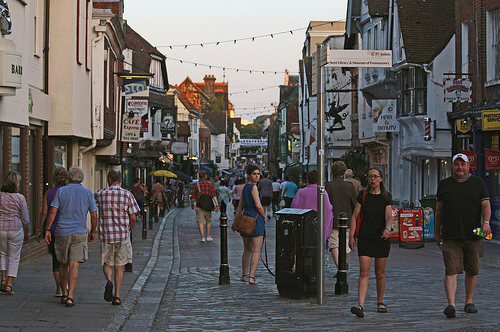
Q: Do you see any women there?
A: Yes, there is a woman.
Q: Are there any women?
A: Yes, there is a woman.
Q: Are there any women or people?
A: Yes, there is a woman.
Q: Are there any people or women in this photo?
A: Yes, there is a woman.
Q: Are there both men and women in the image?
A: Yes, there are both a woman and a man.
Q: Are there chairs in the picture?
A: No, there are no chairs.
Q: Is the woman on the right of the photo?
A: Yes, the woman is on the right of the image.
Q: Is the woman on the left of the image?
A: No, the woman is on the right of the image.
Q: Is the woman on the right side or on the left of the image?
A: The woman is on the right of the image.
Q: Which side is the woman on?
A: The woman is on the right of the image.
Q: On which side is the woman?
A: The woman is on the right of the image.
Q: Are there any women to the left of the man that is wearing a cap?
A: Yes, there is a woman to the left of the man.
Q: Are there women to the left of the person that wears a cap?
A: Yes, there is a woman to the left of the man.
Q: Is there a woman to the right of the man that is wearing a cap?
A: No, the woman is to the left of the man.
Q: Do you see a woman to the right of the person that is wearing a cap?
A: No, the woman is to the left of the man.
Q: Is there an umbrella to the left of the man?
A: No, there is a woman to the left of the man.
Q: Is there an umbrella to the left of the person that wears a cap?
A: No, there is a woman to the left of the man.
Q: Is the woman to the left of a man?
A: Yes, the woman is to the left of a man.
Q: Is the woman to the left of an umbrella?
A: No, the woman is to the left of a man.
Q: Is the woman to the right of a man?
A: No, the woman is to the left of a man.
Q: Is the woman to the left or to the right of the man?
A: The woman is to the left of the man.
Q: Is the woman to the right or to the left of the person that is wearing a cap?
A: The woman is to the left of the man.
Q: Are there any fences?
A: No, there are no fences.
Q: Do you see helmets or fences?
A: No, there are no fences or helmets.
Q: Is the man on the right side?
A: Yes, the man is on the right of the image.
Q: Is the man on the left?
A: No, the man is on the right of the image.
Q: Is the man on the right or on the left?
A: The man is on the right of the image.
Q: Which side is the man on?
A: The man is on the right of the image.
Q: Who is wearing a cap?
A: The man is wearing a cap.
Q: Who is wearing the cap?
A: The man is wearing a cap.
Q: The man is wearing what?
A: The man is wearing a cap.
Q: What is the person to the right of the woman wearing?
A: The man is wearing a cap.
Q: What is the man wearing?
A: The man is wearing a cap.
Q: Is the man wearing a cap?
A: Yes, the man is wearing a cap.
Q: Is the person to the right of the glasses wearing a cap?
A: Yes, the man is wearing a cap.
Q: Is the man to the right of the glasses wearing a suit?
A: No, the man is wearing a cap.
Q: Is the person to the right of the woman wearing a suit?
A: No, the man is wearing a cap.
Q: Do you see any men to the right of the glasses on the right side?
A: Yes, there is a man to the right of the glasses.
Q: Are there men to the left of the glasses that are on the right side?
A: No, the man is to the right of the glasses.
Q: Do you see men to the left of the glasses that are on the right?
A: No, the man is to the right of the glasses.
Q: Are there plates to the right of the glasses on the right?
A: No, there is a man to the right of the glasses.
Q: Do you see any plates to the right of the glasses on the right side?
A: No, there is a man to the right of the glasses.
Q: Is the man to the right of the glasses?
A: Yes, the man is to the right of the glasses.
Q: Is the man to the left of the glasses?
A: No, the man is to the right of the glasses.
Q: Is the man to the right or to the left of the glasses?
A: The man is to the right of the glasses.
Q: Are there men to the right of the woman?
A: Yes, there is a man to the right of the woman.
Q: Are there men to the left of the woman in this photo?
A: No, the man is to the right of the woman.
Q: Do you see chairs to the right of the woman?
A: No, there is a man to the right of the woman.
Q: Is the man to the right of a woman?
A: Yes, the man is to the right of a woman.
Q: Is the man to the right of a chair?
A: No, the man is to the right of a woman.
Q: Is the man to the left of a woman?
A: No, the man is to the right of a woman.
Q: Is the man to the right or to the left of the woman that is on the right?
A: The man is to the right of the woman.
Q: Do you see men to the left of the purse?
A: No, the man is to the right of the purse.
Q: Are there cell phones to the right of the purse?
A: No, there is a man to the right of the purse.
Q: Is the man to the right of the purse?
A: Yes, the man is to the right of the purse.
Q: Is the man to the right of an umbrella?
A: No, the man is to the right of the purse.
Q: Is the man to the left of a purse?
A: No, the man is to the right of a purse.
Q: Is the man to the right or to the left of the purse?
A: The man is to the right of the purse.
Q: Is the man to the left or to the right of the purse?
A: The man is to the right of the purse.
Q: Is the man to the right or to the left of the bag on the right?
A: The man is to the right of the purse.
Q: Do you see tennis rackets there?
A: No, there are no tennis rackets.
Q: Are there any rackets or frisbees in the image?
A: No, there are no rackets or frisbees.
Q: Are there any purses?
A: Yes, there is a purse.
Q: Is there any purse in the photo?
A: Yes, there is a purse.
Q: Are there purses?
A: Yes, there is a purse.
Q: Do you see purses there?
A: Yes, there is a purse.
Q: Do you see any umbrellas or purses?
A: Yes, there is a purse.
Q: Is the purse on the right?
A: Yes, the purse is on the right of the image.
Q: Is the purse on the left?
A: No, the purse is on the right of the image.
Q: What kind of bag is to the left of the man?
A: The bag is a purse.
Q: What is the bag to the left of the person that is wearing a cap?
A: The bag is a purse.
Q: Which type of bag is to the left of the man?
A: The bag is a purse.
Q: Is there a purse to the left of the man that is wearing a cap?
A: Yes, there is a purse to the left of the man.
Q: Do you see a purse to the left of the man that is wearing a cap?
A: Yes, there is a purse to the left of the man.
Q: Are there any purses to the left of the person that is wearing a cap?
A: Yes, there is a purse to the left of the man.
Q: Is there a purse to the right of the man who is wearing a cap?
A: No, the purse is to the left of the man.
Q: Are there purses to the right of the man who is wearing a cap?
A: No, the purse is to the left of the man.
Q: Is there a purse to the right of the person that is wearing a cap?
A: No, the purse is to the left of the man.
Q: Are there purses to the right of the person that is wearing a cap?
A: No, the purse is to the left of the man.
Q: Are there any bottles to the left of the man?
A: No, there is a purse to the left of the man.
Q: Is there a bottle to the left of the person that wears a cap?
A: No, there is a purse to the left of the man.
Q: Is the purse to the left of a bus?
A: No, the purse is to the left of the man.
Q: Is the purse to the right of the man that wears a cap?
A: No, the purse is to the left of the man.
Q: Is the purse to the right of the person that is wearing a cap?
A: No, the purse is to the left of the man.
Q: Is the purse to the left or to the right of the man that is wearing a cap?
A: The purse is to the left of the man.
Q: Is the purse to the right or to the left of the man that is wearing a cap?
A: The purse is to the left of the man.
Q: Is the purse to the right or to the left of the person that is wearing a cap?
A: The purse is to the left of the man.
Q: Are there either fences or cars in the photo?
A: No, there are no fences or cars.